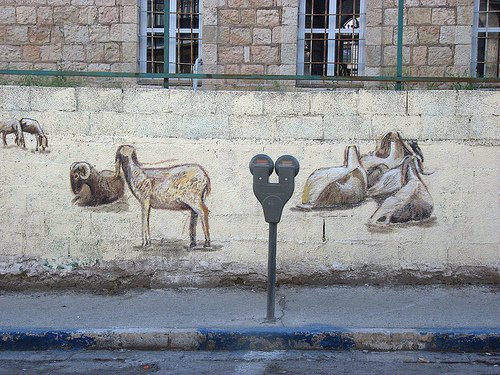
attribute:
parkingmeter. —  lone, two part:
[245, 151, 303, 322]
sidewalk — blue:
[197, 320, 359, 353]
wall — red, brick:
[358, 126, 440, 229]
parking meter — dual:
[275, 145, 307, 209]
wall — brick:
[199, 106, 481, 261]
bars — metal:
[299, 4, 358, 76]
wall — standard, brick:
[2, 1, 499, 86]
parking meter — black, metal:
[248, 153, 298, 324]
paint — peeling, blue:
[6, 321, 97, 349]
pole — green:
[261, 221, 281, 326]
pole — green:
[396, 3, 407, 83]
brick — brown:
[22, 25, 51, 44]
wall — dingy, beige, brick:
[87, 97, 187, 130]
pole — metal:
[243, 223, 315, 321]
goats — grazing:
[52, 135, 224, 251]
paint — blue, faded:
[197, 312, 376, 343]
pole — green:
[2, 63, 491, 90]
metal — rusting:
[307, 3, 354, 76]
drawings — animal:
[102, 103, 432, 273]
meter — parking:
[236, 136, 333, 296]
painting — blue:
[198, 313, 333, 353]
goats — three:
[320, 96, 456, 256]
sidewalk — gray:
[91, 268, 411, 340]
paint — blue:
[428, 340, 496, 359]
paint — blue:
[196, 317, 351, 359]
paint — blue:
[5, 329, 85, 352]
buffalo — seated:
[71, 157, 120, 201]